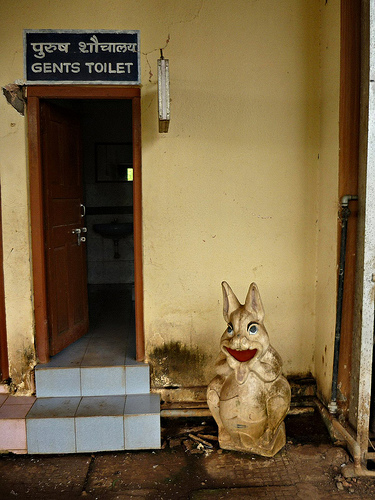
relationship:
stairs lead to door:
[27, 360, 172, 461] [21, 82, 168, 376]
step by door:
[24, 393, 157, 453] [27, 91, 137, 358]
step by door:
[34, 360, 147, 399] [27, 91, 137, 358]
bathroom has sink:
[23, 85, 142, 364] [93, 215, 132, 260]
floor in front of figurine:
[217, 461, 309, 499] [206, 279, 297, 458]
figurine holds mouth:
[206, 279, 297, 458] [219, 341, 261, 362]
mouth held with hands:
[219, 341, 261, 362] [222, 354, 259, 369]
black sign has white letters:
[21, 27, 142, 85] [31, 35, 136, 74]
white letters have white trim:
[31, 35, 136, 74] [15, 30, 141, 85]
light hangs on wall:
[152, 51, 175, 133] [173, 54, 219, 116]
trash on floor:
[194, 439, 210, 450] [2, 411, 372, 498]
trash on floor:
[145, 461, 164, 474] [2, 411, 372, 498]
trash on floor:
[161, 420, 215, 455] [2, 411, 372, 498]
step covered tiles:
[24, 393, 161, 453] [0, 363, 159, 459]